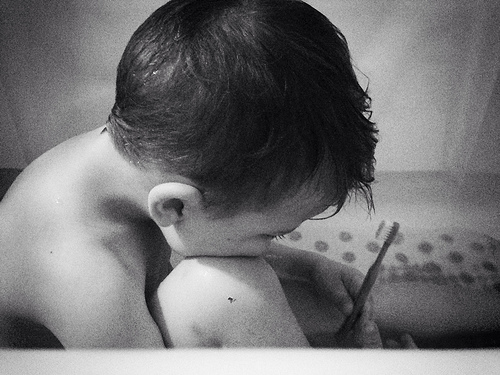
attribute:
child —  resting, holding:
[0, 7, 372, 340]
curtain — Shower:
[369, 14, 485, 278]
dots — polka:
[328, 223, 474, 284]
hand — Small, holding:
[315, 270, 369, 324]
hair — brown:
[109, 9, 371, 203]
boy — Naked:
[8, 8, 405, 338]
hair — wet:
[120, 3, 388, 223]